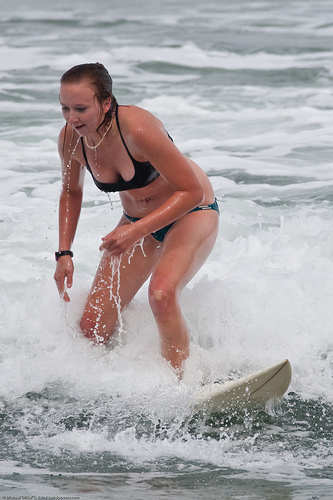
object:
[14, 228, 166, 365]
ocean wave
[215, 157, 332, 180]
waves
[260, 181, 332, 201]
waves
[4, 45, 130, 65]
waves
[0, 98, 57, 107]
waves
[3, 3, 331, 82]
ocean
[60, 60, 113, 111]
hair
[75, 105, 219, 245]
bikini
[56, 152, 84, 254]
arm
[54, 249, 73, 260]
watch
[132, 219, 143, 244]
wrist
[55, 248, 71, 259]
wrist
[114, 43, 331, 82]
wave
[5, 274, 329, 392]
wave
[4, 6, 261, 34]
wave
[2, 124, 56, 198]
wave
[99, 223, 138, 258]
hand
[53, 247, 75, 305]
hand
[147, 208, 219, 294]
thigh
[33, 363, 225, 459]
water splash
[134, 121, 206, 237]
arm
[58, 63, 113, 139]
head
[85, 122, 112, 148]
necklace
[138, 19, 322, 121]
waves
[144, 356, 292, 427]
board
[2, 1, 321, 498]
water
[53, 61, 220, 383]
human